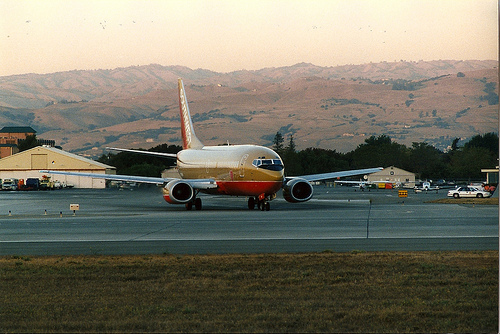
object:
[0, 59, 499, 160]
mountains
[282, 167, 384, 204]
wing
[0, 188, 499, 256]
cement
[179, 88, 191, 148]
airline name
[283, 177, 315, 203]
engine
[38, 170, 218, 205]
wing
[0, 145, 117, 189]
building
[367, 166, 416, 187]
building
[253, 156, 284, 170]
windshield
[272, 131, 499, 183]
trees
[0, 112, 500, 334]
area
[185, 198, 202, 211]
black wheels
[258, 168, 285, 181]
nose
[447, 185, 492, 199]
car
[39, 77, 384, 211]
airplane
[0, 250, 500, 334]
grass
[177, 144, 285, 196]
fuselage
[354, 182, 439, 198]
lot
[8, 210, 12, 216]
object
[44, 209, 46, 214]
object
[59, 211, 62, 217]
object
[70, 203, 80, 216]
object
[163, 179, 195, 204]
engine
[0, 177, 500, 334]
ground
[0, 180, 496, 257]
airport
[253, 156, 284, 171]
cockpit area